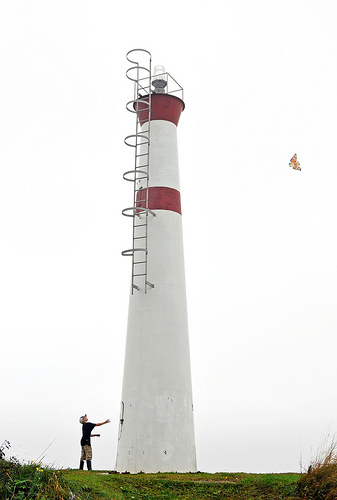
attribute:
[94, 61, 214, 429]
lighthouse — red, white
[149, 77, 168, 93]
light — clear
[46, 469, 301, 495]
grass — green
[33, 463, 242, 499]
flowers — yellow, little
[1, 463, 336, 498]
bank — green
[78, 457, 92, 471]
boots — black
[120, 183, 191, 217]
stripes — red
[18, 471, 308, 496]
grass — green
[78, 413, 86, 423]
hat — white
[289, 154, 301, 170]
kite — orange, black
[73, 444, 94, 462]
pants — brown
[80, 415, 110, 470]
boy — young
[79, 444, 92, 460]
pants — tan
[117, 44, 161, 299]
railing — silver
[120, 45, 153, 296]
ladder — metal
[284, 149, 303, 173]
kite — multi color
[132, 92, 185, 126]
top — red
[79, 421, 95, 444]
shirt — black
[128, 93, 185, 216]
stripes — red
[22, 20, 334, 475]
clouds — white , grey 